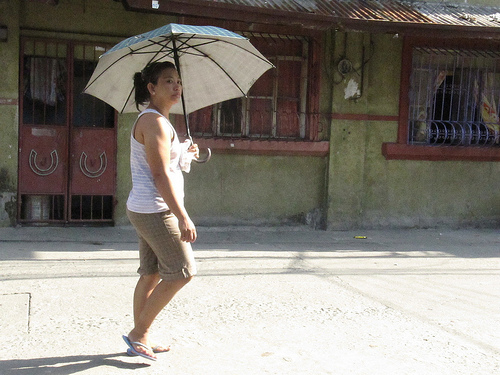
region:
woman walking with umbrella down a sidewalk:
[63, 15, 281, 371]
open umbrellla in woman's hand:
[83, 18, 278, 175]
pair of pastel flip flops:
[122, 323, 174, 365]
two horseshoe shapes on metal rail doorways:
[23, 138, 115, 185]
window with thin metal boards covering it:
[396, 40, 498, 150]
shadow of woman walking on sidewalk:
[3, 335, 152, 372]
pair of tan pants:
[119, 203, 201, 283]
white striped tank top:
[118, 107, 194, 218]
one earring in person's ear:
[147, 88, 162, 100]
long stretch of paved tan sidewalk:
[4, 222, 496, 374]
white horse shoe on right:
[78, 137, 123, 194]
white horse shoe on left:
[26, 137, 71, 184]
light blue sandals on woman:
[111, 314, 165, 373]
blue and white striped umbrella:
[80, 8, 290, 115]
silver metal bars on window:
[416, 67, 493, 124]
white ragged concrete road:
[303, 270, 450, 358]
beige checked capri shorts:
[116, 190, 199, 281]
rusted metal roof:
[361, 4, 438, 30]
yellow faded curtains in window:
[469, 58, 494, 106]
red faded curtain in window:
[266, 50, 310, 122]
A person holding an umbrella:
[76, 21, 278, 364]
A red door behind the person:
[11, 27, 130, 230]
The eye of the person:
[163, 74, 174, 86]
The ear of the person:
[145, 77, 157, 98]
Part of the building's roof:
[365, 1, 451, 16]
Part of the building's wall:
[387, 175, 458, 217]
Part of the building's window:
[414, 68, 476, 122]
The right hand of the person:
[177, 214, 198, 246]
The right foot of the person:
[118, 332, 162, 364]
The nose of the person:
[171, 78, 181, 95]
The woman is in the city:
[22, 10, 480, 371]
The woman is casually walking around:
[35, 10, 478, 367]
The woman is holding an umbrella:
[41, 15, 486, 370]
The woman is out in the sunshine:
[27, 3, 488, 363]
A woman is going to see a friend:
[16, 10, 489, 365]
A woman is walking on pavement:
[15, 2, 495, 372]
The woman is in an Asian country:
[15, 10, 486, 348]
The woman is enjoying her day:
[28, 12, 483, 367]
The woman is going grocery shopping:
[11, 15, 481, 372]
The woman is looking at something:
[12, 7, 472, 373]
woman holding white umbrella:
[126, 59, 198, 364]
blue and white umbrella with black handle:
[87, 21, 275, 163]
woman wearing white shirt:
[125, 58, 196, 363]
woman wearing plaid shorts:
[125, 61, 199, 364]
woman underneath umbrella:
[127, 61, 201, 366]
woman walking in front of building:
[123, 63, 195, 361]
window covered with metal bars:
[409, 46, 498, 147]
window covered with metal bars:
[173, 22, 326, 149]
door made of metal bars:
[17, 34, 68, 228]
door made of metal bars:
[71, 34, 117, 226]